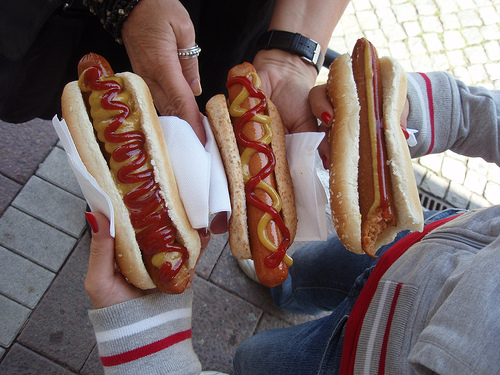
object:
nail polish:
[84, 211, 99, 233]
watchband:
[261, 29, 326, 75]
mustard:
[80, 66, 188, 282]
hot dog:
[225, 61, 289, 288]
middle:
[197, 1, 312, 373]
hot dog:
[352, 36, 398, 258]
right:
[313, 0, 500, 374]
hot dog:
[77, 51, 192, 295]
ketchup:
[82, 68, 188, 280]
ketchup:
[225, 72, 294, 268]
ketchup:
[371, 40, 393, 219]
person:
[0, 0, 354, 193]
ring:
[177, 45, 201, 60]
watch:
[253, 29, 325, 75]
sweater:
[87, 71, 500, 375]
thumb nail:
[83, 211, 98, 233]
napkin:
[200, 116, 330, 242]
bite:
[362, 210, 398, 257]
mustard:
[228, 71, 293, 266]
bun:
[205, 91, 300, 260]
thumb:
[172, 22, 202, 97]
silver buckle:
[300, 37, 321, 65]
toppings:
[79, 40, 390, 278]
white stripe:
[95, 308, 193, 343]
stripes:
[408, 71, 437, 156]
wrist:
[254, 35, 328, 73]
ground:
[2, 1, 499, 374]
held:
[54, 52, 205, 313]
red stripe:
[99, 328, 193, 367]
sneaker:
[237, 258, 261, 283]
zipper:
[423, 233, 486, 250]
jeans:
[234, 208, 468, 375]